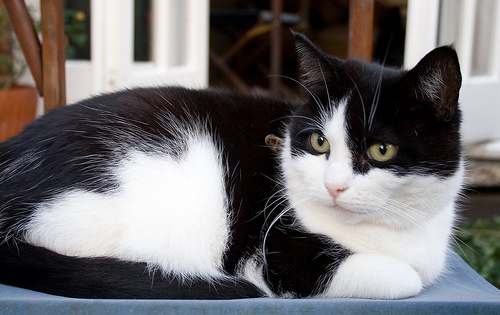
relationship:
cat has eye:
[5, 29, 467, 298] [365, 139, 403, 162]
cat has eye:
[5, 29, 467, 298] [295, 128, 332, 158]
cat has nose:
[5, 29, 467, 298] [321, 172, 350, 199]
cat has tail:
[5, 29, 467, 298] [6, 238, 265, 300]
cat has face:
[5, 29, 467, 298] [276, 26, 470, 231]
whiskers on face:
[257, 167, 322, 263] [276, 26, 470, 231]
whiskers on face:
[267, 63, 415, 132] [276, 26, 470, 231]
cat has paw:
[5, 29, 467, 298] [269, 223, 426, 305]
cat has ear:
[5, 29, 467, 298] [288, 29, 342, 92]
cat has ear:
[5, 29, 467, 298] [408, 45, 465, 120]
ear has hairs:
[288, 29, 342, 92] [299, 48, 323, 88]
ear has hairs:
[408, 45, 465, 120] [422, 72, 444, 106]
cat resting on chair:
[5, 29, 467, 298] [2, 240, 500, 312]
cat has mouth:
[5, 29, 467, 298] [320, 198, 367, 221]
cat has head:
[5, 29, 467, 298] [276, 26, 470, 231]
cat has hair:
[5, 29, 467, 298] [27, 126, 232, 283]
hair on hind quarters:
[27, 126, 232, 283] [0, 87, 261, 298]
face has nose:
[276, 26, 470, 231] [321, 172, 350, 199]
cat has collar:
[5, 29, 467, 298] [261, 131, 284, 154]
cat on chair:
[5, 29, 467, 298] [2, 240, 500, 312]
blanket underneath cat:
[2, 240, 500, 312] [5, 29, 467, 298]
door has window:
[69, 0, 208, 93] [69, 4, 189, 64]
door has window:
[406, 0, 499, 146] [441, 2, 491, 74]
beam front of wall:
[12, 2, 71, 124] [1, 0, 211, 102]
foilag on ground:
[454, 220, 499, 286] [450, 141, 499, 297]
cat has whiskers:
[5, 29, 467, 298] [257, 167, 322, 263]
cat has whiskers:
[5, 29, 467, 298] [267, 63, 415, 132]